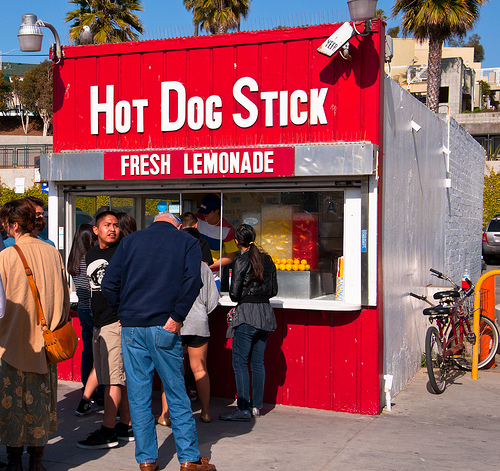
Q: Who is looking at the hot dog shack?
A: The photographer.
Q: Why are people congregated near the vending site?
A: To get food and drinks.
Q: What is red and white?
A: The "Hot Dog Stick.".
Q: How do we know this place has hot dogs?
A: The sign says so.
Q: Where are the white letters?
A: On the red building.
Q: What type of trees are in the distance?
A: Palm trees.